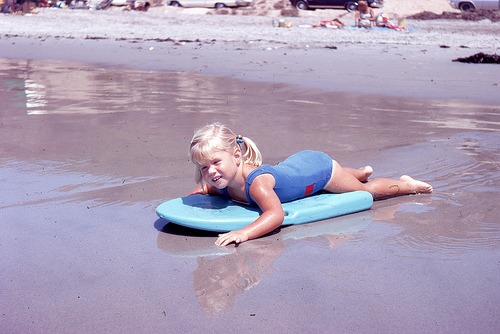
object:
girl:
[185, 122, 434, 247]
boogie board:
[155, 183, 375, 234]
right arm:
[197, 182, 219, 195]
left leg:
[332, 169, 433, 202]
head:
[187, 122, 244, 191]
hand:
[214, 230, 246, 246]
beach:
[1, 0, 497, 98]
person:
[353, 0, 377, 29]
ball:
[376, 12, 389, 27]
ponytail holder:
[236, 137, 243, 143]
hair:
[188, 122, 263, 192]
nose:
[207, 168, 217, 177]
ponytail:
[236, 134, 262, 166]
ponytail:
[194, 162, 205, 196]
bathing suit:
[219, 149, 332, 207]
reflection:
[186, 217, 376, 315]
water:
[0, 51, 499, 333]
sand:
[275, 32, 498, 88]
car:
[290, 0, 384, 11]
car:
[160, 0, 249, 9]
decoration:
[302, 183, 314, 198]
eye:
[213, 160, 221, 165]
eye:
[201, 166, 207, 171]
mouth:
[211, 175, 224, 183]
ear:
[233, 148, 242, 166]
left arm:
[242, 174, 285, 238]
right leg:
[328, 161, 374, 181]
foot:
[399, 175, 434, 195]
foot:
[357, 165, 374, 182]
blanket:
[297, 19, 412, 31]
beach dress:
[358, 10, 373, 25]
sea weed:
[451, 52, 499, 65]